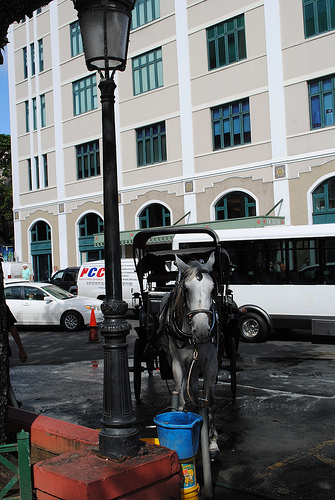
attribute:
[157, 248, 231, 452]
horse — white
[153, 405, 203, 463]
bucket — blue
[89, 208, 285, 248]
awning — light green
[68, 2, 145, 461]
lamp post — black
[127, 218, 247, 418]
carriage — horse-drawn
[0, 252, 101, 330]
car — white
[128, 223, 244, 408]
black carriage — old fashioned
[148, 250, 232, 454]
horse — white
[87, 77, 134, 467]
lampost — black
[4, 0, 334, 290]
building — beige, white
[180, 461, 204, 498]
bucket — yellow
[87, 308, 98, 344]
letter — traffic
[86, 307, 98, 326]
traffic cone — orange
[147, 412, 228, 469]
bucket — blue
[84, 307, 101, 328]
cone — orange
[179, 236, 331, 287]
windows — tinted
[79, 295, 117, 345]
cone — orange